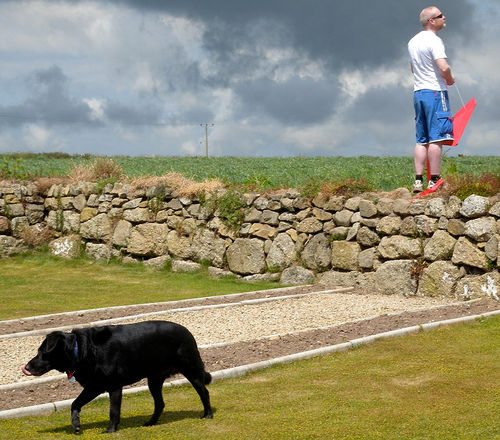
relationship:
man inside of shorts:
[407, 4, 454, 194] [412, 88, 453, 145]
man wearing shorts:
[407, 4, 454, 194] [412, 88, 453, 145]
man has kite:
[407, 4, 454, 194] [447, 99, 477, 148]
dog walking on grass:
[23, 320, 214, 432] [0, 313, 499, 439]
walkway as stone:
[1, 284, 500, 417] [51, 382, 60, 390]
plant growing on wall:
[216, 193, 246, 235] [2, 178, 499, 299]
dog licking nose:
[23, 320, 214, 432] [24, 363, 32, 373]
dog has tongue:
[23, 320, 214, 432] [23, 365, 30, 378]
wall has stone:
[2, 178, 499, 299] [111, 220, 132, 247]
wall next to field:
[2, 178, 499, 299] [2, 150, 499, 195]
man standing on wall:
[407, 4, 454, 194] [2, 178, 499, 299]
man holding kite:
[407, 4, 454, 194] [447, 99, 477, 148]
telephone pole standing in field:
[201, 122, 215, 159] [2, 150, 499, 195]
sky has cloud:
[1, 2, 499, 157] [231, 73, 346, 129]